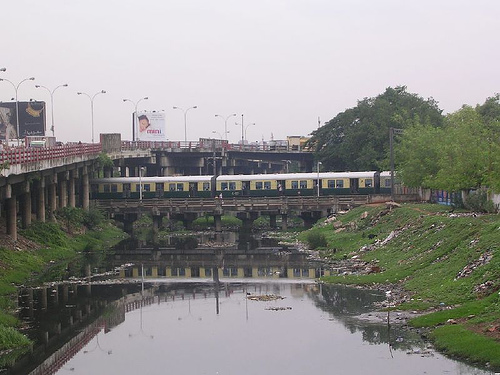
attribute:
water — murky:
[0, 225, 497, 374]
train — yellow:
[73, 161, 450, 230]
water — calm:
[0, 202, 496, 374]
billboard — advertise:
[131, 109, 168, 140]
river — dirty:
[35, 233, 481, 373]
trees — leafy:
[307, 85, 447, 175]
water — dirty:
[28, 227, 383, 296]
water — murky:
[55, 203, 418, 358]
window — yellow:
[166, 182, 183, 192]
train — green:
[95, 171, 392, 194]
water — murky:
[146, 207, 254, 297]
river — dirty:
[20, 200, 448, 374]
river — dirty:
[168, 230, 272, 342]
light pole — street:
[75, 85, 109, 147]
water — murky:
[133, 294, 277, 366]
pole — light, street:
[131, 110, 137, 155]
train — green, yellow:
[90, 158, 420, 218]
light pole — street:
[32, 80, 72, 142]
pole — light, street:
[183, 102, 187, 143]